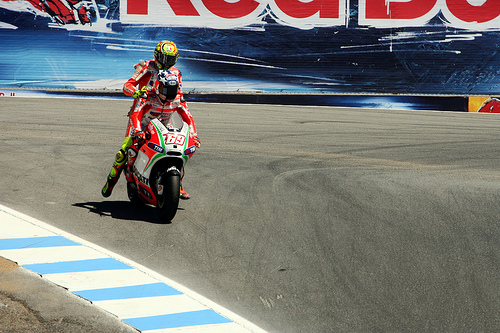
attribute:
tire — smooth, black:
[147, 167, 184, 222]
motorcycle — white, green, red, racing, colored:
[118, 109, 194, 221]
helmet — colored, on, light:
[149, 67, 185, 103]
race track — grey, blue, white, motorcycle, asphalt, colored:
[3, 76, 500, 330]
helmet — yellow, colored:
[152, 39, 179, 68]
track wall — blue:
[1, 2, 492, 110]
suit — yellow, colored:
[130, 60, 191, 94]